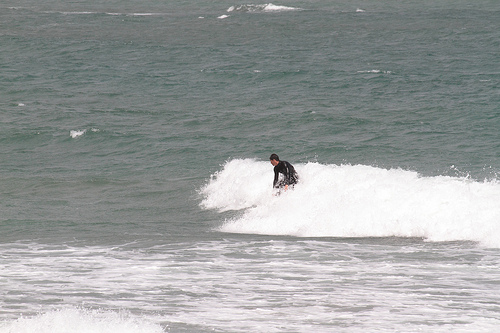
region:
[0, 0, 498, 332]
a large ocean view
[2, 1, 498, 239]
the water is blue green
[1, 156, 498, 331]
the water is white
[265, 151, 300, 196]
the man with black wet suit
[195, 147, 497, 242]
one medium water wave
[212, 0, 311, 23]
a small water wave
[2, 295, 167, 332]
one good splash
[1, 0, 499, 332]
a lot of water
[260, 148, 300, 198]
a man bent down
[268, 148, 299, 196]
a man on a surfboard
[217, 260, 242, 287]
the water is clear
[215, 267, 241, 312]
the water is clear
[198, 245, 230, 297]
the water is clear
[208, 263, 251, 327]
the water is clear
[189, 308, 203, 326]
the water is clear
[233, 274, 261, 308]
the water is clear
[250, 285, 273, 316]
the water is clear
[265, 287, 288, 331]
the water is clear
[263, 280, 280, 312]
the water is clear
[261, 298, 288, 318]
the water is clear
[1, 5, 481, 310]
the ocean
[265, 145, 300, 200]
a young man in the water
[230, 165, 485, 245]
a wave crashing down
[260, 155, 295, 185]
black wet suit on the man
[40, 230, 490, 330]
sea foam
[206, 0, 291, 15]
a wave beginning to crest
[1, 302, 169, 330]
some water splashing up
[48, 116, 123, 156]
a very small wave in the ocean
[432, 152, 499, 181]
water splashing up from a wave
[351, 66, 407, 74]
a very small wave in the water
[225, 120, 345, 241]
man in the water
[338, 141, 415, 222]
white water around the man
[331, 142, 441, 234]
wave coming to the shore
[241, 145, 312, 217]
man surfing in wave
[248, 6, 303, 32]
white wave in the background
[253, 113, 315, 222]
man facing the right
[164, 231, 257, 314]
white suds in water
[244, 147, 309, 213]
man in a wetsuit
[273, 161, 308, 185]
black wetsuit on man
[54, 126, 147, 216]
water next to the man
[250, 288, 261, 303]
the water is clear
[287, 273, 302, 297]
the water is clear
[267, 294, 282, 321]
the water is clear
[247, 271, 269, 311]
the water is clear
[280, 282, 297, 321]
the water is clear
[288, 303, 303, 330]
the water is clear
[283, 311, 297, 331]
the water is clear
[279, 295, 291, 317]
the water is clear